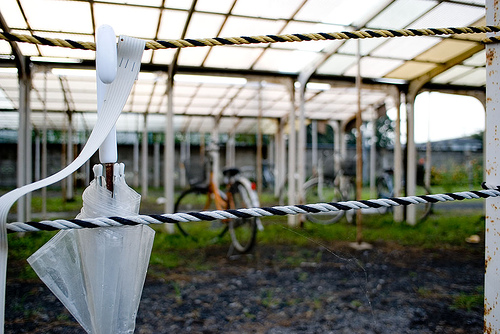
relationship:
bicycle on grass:
[173, 157, 264, 257] [9, 176, 484, 274]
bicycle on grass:
[176, 157, 306, 227] [268, 193, 492, 280]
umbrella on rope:
[33, 32, 145, 332] [0, 25, 497, 42]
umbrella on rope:
[25, 24, 155, 333] [7, 182, 499, 218]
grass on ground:
[157, 187, 491, 238] [151, 200, 469, 327]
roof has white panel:
[1, 3, 498, 142] [366, 0, 441, 29]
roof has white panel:
[1, 3, 498, 142] [248, 45, 315, 78]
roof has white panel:
[1, 3, 498, 142] [93, 2, 160, 42]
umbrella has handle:
[25, 24, 155, 333] [72, 25, 141, 169]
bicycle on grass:
[173, 157, 264, 257] [158, 227, 288, 272]